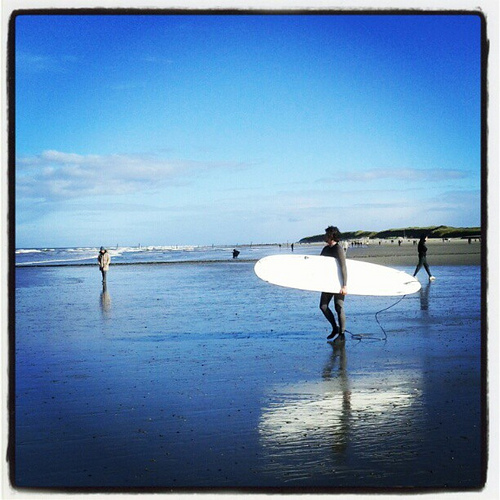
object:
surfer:
[319, 225, 348, 342]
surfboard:
[254, 253, 422, 297]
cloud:
[14, 147, 251, 224]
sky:
[10, 14, 484, 247]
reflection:
[322, 340, 354, 430]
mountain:
[298, 225, 479, 244]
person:
[412, 233, 435, 280]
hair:
[324, 225, 342, 242]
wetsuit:
[319, 243, 347, 334]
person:
[97, 246, 111, 283]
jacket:
[97, 250, 112, 272]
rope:
[345, 295, 406, 341]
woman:
[231, 249, 241, 259]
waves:
[16, 253, 122, 265]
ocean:
[14, 241, 485, 491]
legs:
[334, 294, 346, 334]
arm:
[337, 244, 347, 286]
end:
[405, 272, 423, 296]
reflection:
[258, 371, 423, 447]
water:
[16, 242, 488, 494]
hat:
[100, 246, 106, 251]